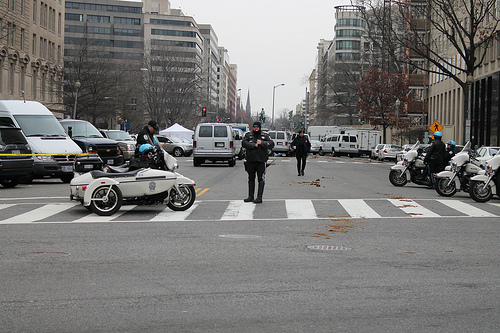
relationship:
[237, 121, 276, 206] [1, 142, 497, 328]
officer in street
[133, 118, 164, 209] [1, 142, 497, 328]
officer in street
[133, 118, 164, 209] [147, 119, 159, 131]
officer with hat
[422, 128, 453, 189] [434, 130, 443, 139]
officer wearing helmet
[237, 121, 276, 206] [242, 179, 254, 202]
officer wearing boots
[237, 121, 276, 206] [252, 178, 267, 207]
officer wearing boots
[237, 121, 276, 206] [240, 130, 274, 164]
officer wearing jacket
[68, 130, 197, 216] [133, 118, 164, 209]
motorcycle for officer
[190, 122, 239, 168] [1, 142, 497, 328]
van on street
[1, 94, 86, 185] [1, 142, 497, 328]
van on street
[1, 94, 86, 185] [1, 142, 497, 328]
van in street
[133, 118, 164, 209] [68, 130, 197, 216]
officer by motorcycle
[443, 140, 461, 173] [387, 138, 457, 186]
person on motorcycle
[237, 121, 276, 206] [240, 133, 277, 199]
officer wearing uniform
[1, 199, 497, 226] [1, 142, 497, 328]
crosswalk on street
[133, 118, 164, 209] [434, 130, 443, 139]
officer wearing helmet